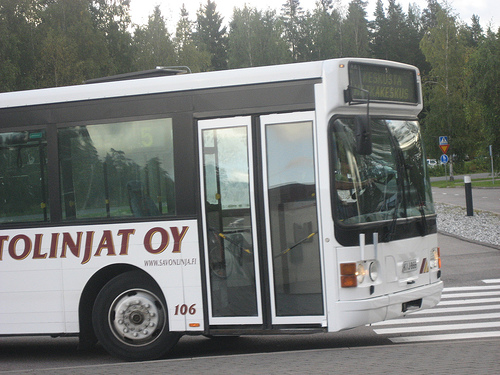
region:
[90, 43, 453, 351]
Bus parked on the road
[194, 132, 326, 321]
Doors on the bus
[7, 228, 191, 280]
Writing on side of the bus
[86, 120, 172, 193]
Reflection on the glass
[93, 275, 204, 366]
Wheel on the bus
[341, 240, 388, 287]
Headlights on the bus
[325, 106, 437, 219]
Front windshield on bus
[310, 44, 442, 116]
Writing on the sign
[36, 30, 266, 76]
Trees behind the bus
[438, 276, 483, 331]
Paint on the ground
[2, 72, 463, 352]
bus on roadway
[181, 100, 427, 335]
glass doors on bus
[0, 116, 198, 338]
writing on side of bus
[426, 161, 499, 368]
bike path near roadway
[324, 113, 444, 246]
bus windshield with wipes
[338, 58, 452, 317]
light up sign on front of bus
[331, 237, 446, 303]
headlights on front of bus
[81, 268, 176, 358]
wheel turning away from pavement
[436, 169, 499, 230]
pole by bike path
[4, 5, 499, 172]
line of trees by road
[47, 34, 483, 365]
the bus is white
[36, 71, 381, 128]
the bus is white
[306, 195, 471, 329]
the bus is white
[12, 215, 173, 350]
the bus is white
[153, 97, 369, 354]
bus door is closed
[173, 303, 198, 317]
number identifying a bus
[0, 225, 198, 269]
the name of a bus company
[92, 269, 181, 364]
right front tire on a bus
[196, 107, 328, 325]
two glass doors on a bus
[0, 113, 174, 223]
two glass windows on a bus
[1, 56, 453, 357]
large white bus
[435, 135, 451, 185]
red and blue signs along a road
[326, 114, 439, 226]
front windshield on a bus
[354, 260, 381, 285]
headlights on a bus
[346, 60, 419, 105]
sign identifying the rout of a bus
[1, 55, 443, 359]
white bus pulling up to curb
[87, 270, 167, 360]
front left wheel of bus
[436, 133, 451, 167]
yield sign between two blue signs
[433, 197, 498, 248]
median covered in gravel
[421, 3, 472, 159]
tall deciduous tree beyond signs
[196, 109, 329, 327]
double door of bus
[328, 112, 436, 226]
windshield of bus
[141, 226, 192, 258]
red "oy" printed on bus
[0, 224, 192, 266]
red letters with yellow highlights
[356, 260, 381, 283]
two right headlights of bus